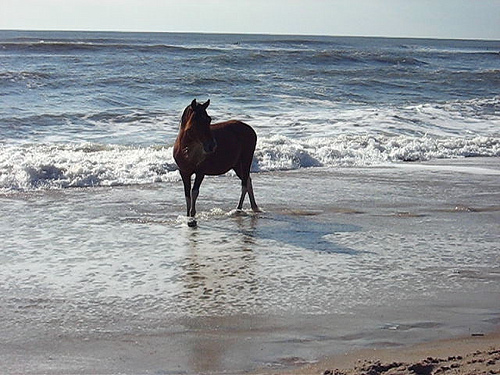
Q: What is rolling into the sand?
A: Waves.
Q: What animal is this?
A: Horse.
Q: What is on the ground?
A: Sand.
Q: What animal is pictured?
A: Horse.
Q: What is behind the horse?
A: Ocean.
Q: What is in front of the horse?
A: Sand.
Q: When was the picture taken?
A: During day hours.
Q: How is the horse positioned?
A: Standing.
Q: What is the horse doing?
A: Standing in the water.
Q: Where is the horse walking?
A: Towards the camera.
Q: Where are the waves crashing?
A: On the beach.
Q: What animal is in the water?
A: Horse.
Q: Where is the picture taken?
A: Beach.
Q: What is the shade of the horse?
A: Brown.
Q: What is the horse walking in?
A: Water.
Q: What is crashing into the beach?
A: Waves.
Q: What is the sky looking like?
A: Clear.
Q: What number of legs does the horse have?
A: 4.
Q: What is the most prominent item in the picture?
A: Water.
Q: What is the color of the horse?
A: Brown.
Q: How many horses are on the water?
A: One.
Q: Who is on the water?
A: A horse.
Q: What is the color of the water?
A: Blue.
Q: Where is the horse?
A: In the water.